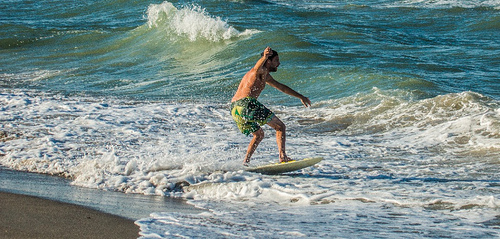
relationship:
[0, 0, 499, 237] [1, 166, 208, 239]
ocean touching shore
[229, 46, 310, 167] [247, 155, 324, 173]
man on surfboard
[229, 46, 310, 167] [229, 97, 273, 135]
man wearing swim trunks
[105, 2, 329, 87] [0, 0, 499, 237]
wave in ocean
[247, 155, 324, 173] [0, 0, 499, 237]
surfboard in ocean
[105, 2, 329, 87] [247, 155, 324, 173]
wave behind surfboard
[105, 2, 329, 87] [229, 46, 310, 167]
wave near man